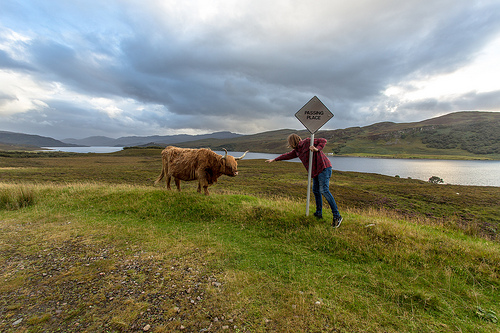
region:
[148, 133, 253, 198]
Bull on green grass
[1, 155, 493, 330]
Field is cover with green grass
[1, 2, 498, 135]
Sky is cloudy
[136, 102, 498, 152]
Hill in other side of water body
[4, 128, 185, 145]
Hills on the background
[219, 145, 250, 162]
Horns of bull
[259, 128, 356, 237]
Woman wears red sweter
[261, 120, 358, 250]
Woman wears blue jean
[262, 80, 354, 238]
Woman holds a sign in his left hand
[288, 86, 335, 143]
Sign is diamond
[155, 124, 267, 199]
The cow is brown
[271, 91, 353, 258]
A person reaching for the cow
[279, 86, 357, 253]
A person standing by the sign.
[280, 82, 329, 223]
The sign is black and white.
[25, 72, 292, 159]
Mountains in the background.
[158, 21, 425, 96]
The sky is overcast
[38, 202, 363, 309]
The grass is green.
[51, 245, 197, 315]
The ground has pebbles and rocks.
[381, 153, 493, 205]
The lake is in the background.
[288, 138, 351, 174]
The shirt is red.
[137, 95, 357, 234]
woman feeding a cow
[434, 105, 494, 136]
rolling hills in the background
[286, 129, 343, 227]
woman wearing blue jeans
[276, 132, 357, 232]
woman wearing a red plaid shirt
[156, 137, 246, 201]
a brown cow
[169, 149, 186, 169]
shaggy brown fur on the cow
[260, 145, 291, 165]
an arm reaching out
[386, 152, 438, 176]
a cool blue lake next to hills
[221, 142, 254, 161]
long white horns on the cow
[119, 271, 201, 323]
rocks scattered on the ground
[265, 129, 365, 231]
the man with red colored shirt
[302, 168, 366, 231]
the blue colored jeans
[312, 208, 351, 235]
the pair of colored shoes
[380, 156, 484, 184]
the river in middle of two hills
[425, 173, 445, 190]
a small tree on the river side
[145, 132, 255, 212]
a brown colored buffalo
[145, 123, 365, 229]
a man offering a buffalo to eat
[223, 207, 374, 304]
the green grass in the fields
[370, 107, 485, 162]
the hills on the side of a river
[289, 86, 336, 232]
the white colored sign board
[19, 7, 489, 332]
a cloudy day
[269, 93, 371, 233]
a person holding a sign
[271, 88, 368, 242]
a person holds a sign in a field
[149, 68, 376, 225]
a person holds his hand out to an animal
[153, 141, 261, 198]
a brown furry animal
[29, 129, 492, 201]
water runs through the grassland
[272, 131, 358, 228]
the person is wearing jeans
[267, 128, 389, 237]
the person is reaching his right hand out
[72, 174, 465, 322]
the grass is green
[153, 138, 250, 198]
the animal has horns